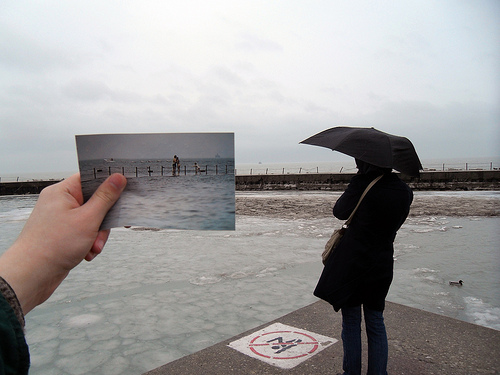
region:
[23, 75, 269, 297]
matching a photo to the scene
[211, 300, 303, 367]
a no swimming sign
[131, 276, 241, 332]
the water is icy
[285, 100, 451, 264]
the umbrella is black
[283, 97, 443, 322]
the purse is tan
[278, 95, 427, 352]
the coat is black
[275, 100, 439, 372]
the jeans are blue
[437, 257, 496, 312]
a duck in the water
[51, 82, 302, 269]
there is a person in the photo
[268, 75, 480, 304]
the sky is overcast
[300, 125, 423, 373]
A person with an umbrella on the head.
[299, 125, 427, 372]
A person with an opened umbrella.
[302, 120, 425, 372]
A lady in blue jeans.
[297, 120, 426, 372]
A lady in a black trench coat.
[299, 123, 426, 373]
A woman covered with a black umbrella.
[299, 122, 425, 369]
A woman standing.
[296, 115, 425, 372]
A lady carrying a sling bag.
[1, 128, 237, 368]
A person holding a photograph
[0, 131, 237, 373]
A person holding a photo with the right hand.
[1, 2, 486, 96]
A cloudy sky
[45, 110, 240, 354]
hand is holding a picture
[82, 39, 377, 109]
the sky is overcast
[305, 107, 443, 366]
a lady carrying an umbrella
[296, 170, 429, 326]
woman is wearing a shirt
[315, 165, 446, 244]
the shirt has long sleeves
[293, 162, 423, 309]
the bag is brown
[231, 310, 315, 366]
a sign on the ground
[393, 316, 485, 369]
the ground is brown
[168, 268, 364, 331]
the water is murky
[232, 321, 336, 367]
the warning sign on the ground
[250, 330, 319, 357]
the red circle on the ground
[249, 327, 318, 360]
the no swimming warning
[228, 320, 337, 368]
the white painted square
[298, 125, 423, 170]
the opened black umbrella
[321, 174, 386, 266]
the light colored bag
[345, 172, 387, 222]
the strap of the light colored bag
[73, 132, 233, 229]
the picture being held up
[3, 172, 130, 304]
the hand holding the picture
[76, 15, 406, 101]
the opened sky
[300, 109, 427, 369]
The woman is wearing black.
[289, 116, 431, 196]
She has an umbrella.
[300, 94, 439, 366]
She is wearing jeans.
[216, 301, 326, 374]
No swimming sign.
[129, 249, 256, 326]
The water is dirty.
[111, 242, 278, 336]
The water is calm.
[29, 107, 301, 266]
The picture is similar.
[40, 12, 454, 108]
The sky is cloudy.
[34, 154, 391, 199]
The pier is long.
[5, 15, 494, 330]
They are by a water source.